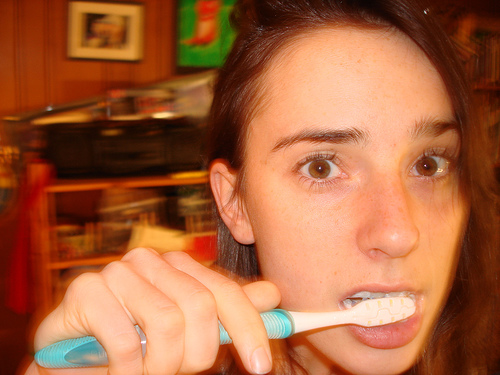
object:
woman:
[26, 0, 498, 374]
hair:
[206, 1, 500, 374]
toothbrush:
[32, 296, 418, 370]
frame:
[65, 0, 142, 61]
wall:
[2, 2, 174, 121]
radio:
[35, 111, 206, 175]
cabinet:
[26, 165, 217, 355]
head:
[189, 1, 479, 373]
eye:
[289, 152, 353, 181]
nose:
[358, 157, 419, 258]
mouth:
[340, 282, 432, 349]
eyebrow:
[272, 128, 369, 154]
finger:
[37, 272, 146, 375]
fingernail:
[248, 348, 274, 374]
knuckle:
[121, 247, 163, 266]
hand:
[34, 248, 281, 374]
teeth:
[345, 291, 420, 313]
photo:
[1, 1, 499, 374]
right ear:
[209, 160, 254, 244]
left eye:
[410, 154, 459, 180]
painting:
[177, 0, 237, 67]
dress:
[0, 157, 52, 317]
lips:
[336, 282, 425, 349]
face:
[242, 26, 472, 373]